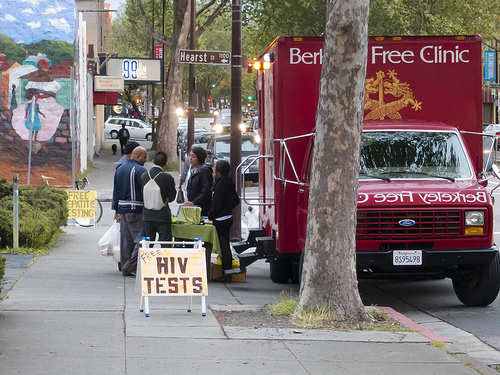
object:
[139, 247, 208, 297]
hiv test sign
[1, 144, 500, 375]
sidewalk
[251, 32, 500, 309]
truck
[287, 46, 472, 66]
berkeley free clinic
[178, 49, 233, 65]
street sign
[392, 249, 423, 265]
license plate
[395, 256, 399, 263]
blue numbers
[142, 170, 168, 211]
backpack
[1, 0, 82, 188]
mural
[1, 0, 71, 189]
wall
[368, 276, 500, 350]
street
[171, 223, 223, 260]
tablecloth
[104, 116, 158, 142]
station wagon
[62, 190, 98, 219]
sign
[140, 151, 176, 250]
man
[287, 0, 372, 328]
tree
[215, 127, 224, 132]
headlights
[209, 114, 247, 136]
car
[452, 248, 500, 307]
tire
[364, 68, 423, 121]
dragons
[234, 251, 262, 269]
steps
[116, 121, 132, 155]
people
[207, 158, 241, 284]
employees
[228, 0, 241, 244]
pole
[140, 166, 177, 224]
sweater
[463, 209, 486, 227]
lights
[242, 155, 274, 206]
support rails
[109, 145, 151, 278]
man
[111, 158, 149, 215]
sweater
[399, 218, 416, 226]
ford logo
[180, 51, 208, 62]
hearst